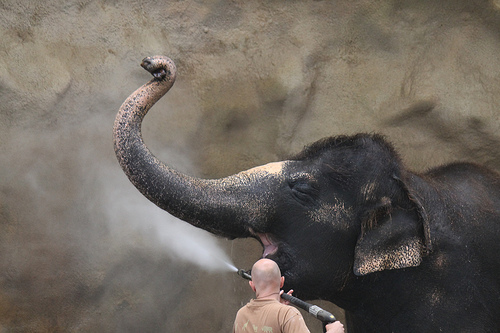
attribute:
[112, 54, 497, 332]
elephant — black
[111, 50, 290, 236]
trunk — up, black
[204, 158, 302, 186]
patch — yellow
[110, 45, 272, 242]
trunk — curledd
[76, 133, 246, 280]
spary — water, powerful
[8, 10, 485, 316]
wall — grey, rock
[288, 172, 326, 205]
eyes — closed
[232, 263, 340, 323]
water gun — blak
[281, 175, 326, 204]
eye — elephant, closed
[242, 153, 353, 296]
face — elephants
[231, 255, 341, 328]
man — bald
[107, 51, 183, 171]
end — curled up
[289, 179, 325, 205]
eye — closed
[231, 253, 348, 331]
man — hairless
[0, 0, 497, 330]
wall — brown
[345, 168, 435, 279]
ear — discolored, black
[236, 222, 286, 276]
mouth — open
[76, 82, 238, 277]
water — misty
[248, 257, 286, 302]
head — bald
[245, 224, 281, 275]
mouth — open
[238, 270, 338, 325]
hose — black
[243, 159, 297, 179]
spot — white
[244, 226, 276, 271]
mouth — pink